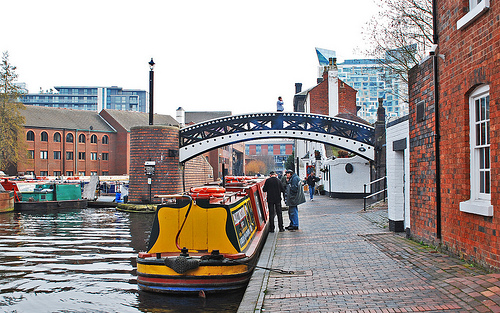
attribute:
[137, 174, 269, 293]
boats — docked, yellow, black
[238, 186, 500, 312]
walkway — brick, red, wet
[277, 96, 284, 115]
person — standing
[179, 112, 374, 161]
overpass — blue, white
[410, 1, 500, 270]
building — brick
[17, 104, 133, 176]
building — brick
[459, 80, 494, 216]
window — white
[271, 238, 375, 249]
lines — red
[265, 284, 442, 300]
lines — red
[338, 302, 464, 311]
lines — red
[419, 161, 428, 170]
bricks — red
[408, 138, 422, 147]
bricks — black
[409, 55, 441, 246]
wall — brick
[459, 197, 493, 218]
windowsill — large, white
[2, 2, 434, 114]
sky — clear, cloudy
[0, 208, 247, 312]
water — clean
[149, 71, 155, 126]
post — large, black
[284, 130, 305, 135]
spots — black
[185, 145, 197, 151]
spots — black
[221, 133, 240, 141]
spots — black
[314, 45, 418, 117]
building — tall, blue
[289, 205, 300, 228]
jeans — blue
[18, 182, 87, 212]
boat — turquoise, docked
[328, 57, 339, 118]
chimney — white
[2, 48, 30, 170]
tree — green, leafy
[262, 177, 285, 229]
clothes — black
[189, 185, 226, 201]
lifesaver — red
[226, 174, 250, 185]
lifesaver — red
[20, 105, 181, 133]
roof — gray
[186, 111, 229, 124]
roof — gray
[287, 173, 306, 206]
jacket — green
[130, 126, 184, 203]
pillar — brick